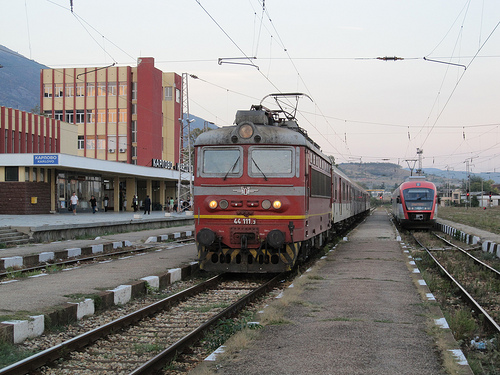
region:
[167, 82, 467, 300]
Two trains on railroad tracks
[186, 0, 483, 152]
Wires above two trains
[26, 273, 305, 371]
Railroad tracks on top of rock gravel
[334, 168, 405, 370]
Pathway between two railroad tracks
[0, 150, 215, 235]
People near railroad tracks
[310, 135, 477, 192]
Hills behind railroad tracks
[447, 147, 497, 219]
Red traffic lights for trains crossing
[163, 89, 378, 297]
Older model train with headlights on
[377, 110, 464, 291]
Newer model train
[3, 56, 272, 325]
Buildings next to train station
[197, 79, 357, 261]
red train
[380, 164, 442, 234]
red train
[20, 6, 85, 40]
white clouds in blue sky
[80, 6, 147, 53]
white clouds in blue sky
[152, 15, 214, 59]
white clouds in blue sky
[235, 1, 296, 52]
white clouds in blue sky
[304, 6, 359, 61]
white clouds in blue sky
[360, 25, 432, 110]
white clouds in blue sky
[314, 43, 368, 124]
white clouds in blue sky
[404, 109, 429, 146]
white clouds in blue sky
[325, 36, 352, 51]
white clouds in blue sky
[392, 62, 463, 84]
white clouds in blue sky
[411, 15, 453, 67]
white clouds in blue sky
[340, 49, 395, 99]
white clouds in blue sky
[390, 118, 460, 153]
white clouds in blue sky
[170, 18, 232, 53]
white clouds in blue sky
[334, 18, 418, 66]
white clouds in blue sky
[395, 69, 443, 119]
white clouds in blue sky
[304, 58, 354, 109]
white clouds in blue sky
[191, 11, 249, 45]
white clouds in blue sky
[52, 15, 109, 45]
white clouds in blue sky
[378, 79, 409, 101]
white clouds in blue sky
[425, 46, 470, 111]
white clouds in blue sky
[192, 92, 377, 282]
train is on railroad tracks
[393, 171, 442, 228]
train is on railroad tracks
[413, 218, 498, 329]
railroad tracks are under a train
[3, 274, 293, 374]
railroad tracks are under a train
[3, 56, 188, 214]
building is in background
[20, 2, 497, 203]
powerlines hang overhead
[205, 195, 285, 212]
headlights are on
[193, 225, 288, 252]
bumpers are attached to front of train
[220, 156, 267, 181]
windshield wipers are turned off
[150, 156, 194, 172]
sign is attached to front of building